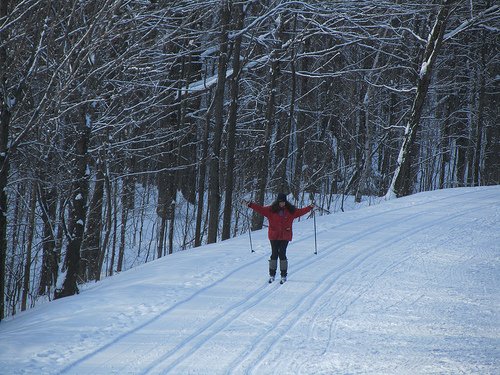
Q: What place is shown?
A: It is a field.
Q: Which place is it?
A: It is a field.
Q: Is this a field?
A: Yes, it is a field.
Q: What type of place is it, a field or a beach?
A: It is a field.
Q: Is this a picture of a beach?
A: No, the picture is showing a field.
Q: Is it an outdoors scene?
A: Yes, it is outdoors.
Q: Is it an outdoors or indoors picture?
A: It is outdoors.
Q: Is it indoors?
A: No, it is outdoors.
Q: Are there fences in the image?
A: No, there are no fences.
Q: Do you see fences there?
A: No, there are no fences.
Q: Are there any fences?
A: No, there are no fences.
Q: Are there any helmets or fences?
A: No, there are no fences or helmets.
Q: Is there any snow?
A: Yes, there is snow.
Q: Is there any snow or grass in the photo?
A: Yes, there is snow.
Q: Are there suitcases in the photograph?
A: No, there are no suitcases.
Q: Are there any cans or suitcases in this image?
A: No, there are no suitcases or cans.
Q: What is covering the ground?
A: The snow is covering the ground.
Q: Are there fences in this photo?
A: No, there are no fences.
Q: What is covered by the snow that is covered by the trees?
A: The ground is covered by the snow.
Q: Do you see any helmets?
A: No, there are no helmets.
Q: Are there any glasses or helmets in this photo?
A: No, there are no helmets or glasses.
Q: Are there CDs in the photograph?
A: No, there are no cds.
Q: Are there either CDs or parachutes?
A: No, there are no CDs or parachutes.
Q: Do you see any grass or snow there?
A: Yes, there is snow.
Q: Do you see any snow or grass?
A: Yes, there is snow.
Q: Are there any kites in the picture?
A: No, there are no kites.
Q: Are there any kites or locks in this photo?
A: No, there are no kites or locks.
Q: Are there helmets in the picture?
A: No, there are no helmets.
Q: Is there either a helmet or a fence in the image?
A: No, there are no helmets or fences.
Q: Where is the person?
A: The person is on the snow.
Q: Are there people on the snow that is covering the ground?
A: Yes, there is a person on the snow.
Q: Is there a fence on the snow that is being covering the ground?
A: No, there is a person on the snow.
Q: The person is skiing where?
A: The person is skiing on the hill.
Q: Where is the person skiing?
A: The person is skiing on the hill.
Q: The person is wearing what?
A: The person is wearing a jacket.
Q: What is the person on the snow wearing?
A: The person is wearing a jacket.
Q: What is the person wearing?
A: The person is wearing a jacket.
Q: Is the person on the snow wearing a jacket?
A: Yes, the person is wearing a jacket.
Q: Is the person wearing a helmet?
A: No, the person is wearing a jacket.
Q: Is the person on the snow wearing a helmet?
A: No, the person is wearing a jacket.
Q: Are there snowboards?
A: No, there are no snowboards.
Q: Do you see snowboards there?
A: No, there are no snowboards.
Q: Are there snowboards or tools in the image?
A: No, there are no snowboards or tools.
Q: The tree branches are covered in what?
A: The tree branches are covered in snow.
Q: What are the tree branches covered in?
A: The tree branches are covered in snow.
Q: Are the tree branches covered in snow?
A: Yes, the tree branches are covered in snow.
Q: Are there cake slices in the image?
A: No, there are no cake slices.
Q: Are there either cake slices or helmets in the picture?
A: No, there are no cake slices or helmets.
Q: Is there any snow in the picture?
A: Yes, there is snow.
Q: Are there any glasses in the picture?
A: No, there are no glasses.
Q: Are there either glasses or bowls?
A: No, there are no glasses or bowls.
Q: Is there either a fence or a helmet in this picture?
A: No, there are no fences or helmets.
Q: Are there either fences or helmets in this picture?
A: No, there are no fences or helmets.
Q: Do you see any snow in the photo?
A: Yes, there is snow.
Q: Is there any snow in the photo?
A: Yes, there is snow.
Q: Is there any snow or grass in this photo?
A: Yes, there is snow.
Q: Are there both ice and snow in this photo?
A: No, there is snow but no ice.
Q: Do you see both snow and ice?
A: No, there is snow but no ice.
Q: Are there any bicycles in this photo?
A: No, there are no bicycles.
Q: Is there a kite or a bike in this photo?
A: No, there are no bikes or kites.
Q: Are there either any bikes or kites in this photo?
A: No, there are no bikes or kites.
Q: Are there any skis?
A: Yes, there are skis.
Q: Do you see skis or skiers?
A: Yes, there are skis.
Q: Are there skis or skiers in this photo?
A: Yes, there are skis.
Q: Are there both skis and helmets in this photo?
A: No, there are skis but no helmets.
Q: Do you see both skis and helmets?
A: No, there are skis but no helmets.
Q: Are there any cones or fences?
A: No, there are no fences or cones.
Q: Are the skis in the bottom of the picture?
A: Yes, the skis are in the bottom of the image.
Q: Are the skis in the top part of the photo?
A: No, the skis are in the bottom of the image.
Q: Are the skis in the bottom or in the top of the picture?
A: The skis are in the bottom of the image.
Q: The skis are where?
A: The skis are on the snow.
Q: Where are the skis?
A: The skis are on the snow.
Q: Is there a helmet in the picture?
A: No, there are no helmets.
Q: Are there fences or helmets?
A: No, there are no helmets or fences.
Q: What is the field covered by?
A: The field is covered by the snow.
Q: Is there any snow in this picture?
A: Yes, there is snow.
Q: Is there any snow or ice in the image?
A: Yes, there is snow.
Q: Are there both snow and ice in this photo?
A: No, there is snow but no ice.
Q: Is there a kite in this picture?
A: No, there are no kites.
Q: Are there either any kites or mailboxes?
A: No, there are no kites or mailboxes.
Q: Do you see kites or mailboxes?
A: No, there are no kites or mailboxes.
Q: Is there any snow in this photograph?
A: Yes, there is snow.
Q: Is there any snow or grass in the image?
A: Yes, there is snow.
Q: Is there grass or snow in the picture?
A: Yes, there is snow.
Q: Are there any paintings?
A: No, there are no paintings.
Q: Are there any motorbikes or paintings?
A: No, there are no paintings or motorbikes.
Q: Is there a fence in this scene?
A: No, there are no fences.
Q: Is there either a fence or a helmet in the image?
A: No, there are no fences or helmets.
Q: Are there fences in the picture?
A: No, there are no fences.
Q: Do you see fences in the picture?
A: No, there are no fences.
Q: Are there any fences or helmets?
A: No, there are no fences or helmets.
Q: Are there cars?
A: No, there are no cars.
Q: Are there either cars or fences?
A: No, there are no cars or fences.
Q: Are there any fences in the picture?
A: No, there are no fences.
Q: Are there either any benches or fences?
A: No, there are no fences or benches.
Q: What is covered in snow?
A: The street is covered in snow.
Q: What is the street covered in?
A: The street is covered in snow.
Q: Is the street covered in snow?
A: Yes, the street is covered in snow.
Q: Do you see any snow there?
A: Yes, there is snow.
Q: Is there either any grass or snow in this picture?
A: Yes, there is snow.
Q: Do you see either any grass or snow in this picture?
A: Yes, there is snow.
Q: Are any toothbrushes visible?
A: No, there are no toothbrushes.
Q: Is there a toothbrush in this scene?
A: No, there are no toothbrushes.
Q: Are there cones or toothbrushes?
A: No, there are no toothbrushes or cones.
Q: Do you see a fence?
A: No, there are no fences.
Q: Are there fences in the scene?
A: No, there are no fences.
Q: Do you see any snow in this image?
A: Yes, there is snow.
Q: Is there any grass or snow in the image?
A: Yes, there is snow.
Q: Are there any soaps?
A: No, there are no soaps.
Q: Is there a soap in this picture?
A: No, there are no soaps.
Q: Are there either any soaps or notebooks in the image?
A: No, there are no soaps or notebooks.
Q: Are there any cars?
A: No, there are no cars.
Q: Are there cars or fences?
A: No, there are no cars or fences.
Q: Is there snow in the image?
A: Yes, there is snow.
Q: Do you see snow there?
A: Yes, there is snow.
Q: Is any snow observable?
A: Yes, there is snow.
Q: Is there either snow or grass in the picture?
A: Yes, there is snow.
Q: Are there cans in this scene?
A: No, there are no cans.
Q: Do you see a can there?
A: No, there are no cans.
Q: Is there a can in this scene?
A: No, there are no cans.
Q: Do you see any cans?
A: No, there are no cans.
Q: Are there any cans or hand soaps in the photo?
A: No, there are no cans or hand soaps.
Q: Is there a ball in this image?
A: No, there are no balls.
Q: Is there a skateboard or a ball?
A: No, there are no balls or skateboards.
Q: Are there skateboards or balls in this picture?
A: No, there are no balls or skateboards.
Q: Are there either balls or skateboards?
A: No, there are no balls or skateboards.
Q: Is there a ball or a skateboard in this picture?
A: No, there are no balls or skateboards.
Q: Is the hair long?
A: Yes, the hair is long.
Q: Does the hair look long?
A: Yes, the hair is long.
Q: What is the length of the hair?
A: The hair is long.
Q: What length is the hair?
A: The hair is long.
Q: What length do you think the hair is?
A: The hair is long.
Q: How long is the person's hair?
A: The hair is long.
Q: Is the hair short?
A: No, the hair is long.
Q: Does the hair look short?
A: No, the hair is long.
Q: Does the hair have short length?
A: No, the hair is long.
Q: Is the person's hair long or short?
A: The hair is long.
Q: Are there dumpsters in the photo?
A: No, there are no dumpsters.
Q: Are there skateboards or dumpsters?
A: No, there are no dumpsters or skateboards.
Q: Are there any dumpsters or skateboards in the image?
A: No, there are no dumpsters or skateboards.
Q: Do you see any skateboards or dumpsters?
A: No, there are no dumpsters or skateboards.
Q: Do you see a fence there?
A: No, there are no fences.